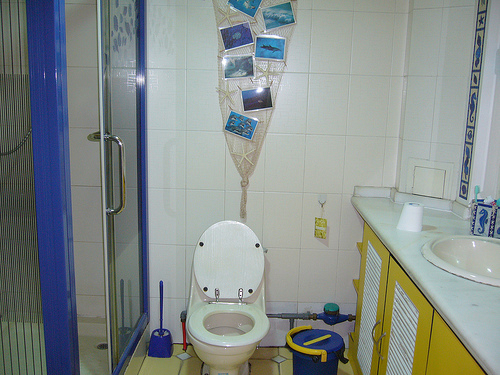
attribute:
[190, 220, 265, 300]
toilet lid — up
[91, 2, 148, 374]
door — shower, open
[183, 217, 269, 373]
toilet — white